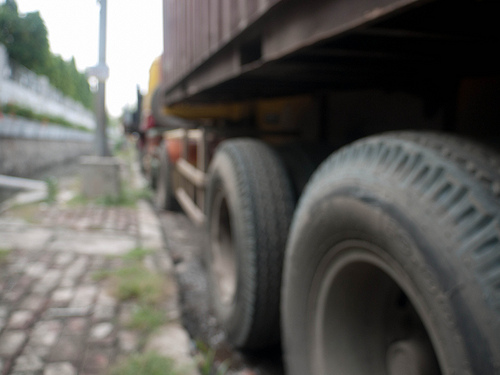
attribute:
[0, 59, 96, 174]
stone wall — stone 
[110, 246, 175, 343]
grass — blurred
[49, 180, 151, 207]
grass — blurred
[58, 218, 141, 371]
sidewalk — red, brick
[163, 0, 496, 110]
container — metallic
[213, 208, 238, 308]
hub — cap, dark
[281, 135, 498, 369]
tire — large , black , rubber, gray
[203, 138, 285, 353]
wheel — black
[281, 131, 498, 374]
wheel — black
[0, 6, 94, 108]
trees — tall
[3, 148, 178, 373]
walkway — brick 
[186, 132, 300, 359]
tire — gray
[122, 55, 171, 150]
truck — yellow, red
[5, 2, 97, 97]
trees — green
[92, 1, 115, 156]
light pole — metal 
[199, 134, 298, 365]
tire — large , black , gray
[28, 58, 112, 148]
wall — white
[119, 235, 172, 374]
grass — green 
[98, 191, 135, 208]
grass — blurred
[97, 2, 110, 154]
pole — metal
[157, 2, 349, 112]
metal top — metal 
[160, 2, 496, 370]
truck — large, metallic, brown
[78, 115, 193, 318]
grass — blurred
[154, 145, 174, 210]
tire — gray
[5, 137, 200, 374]
walkway — brick 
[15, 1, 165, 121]
sky — bright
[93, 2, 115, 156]
pole — silver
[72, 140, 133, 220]
base — concrete 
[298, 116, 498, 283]
tread — rubber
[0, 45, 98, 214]
wall — brick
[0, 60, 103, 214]
wall — brick 